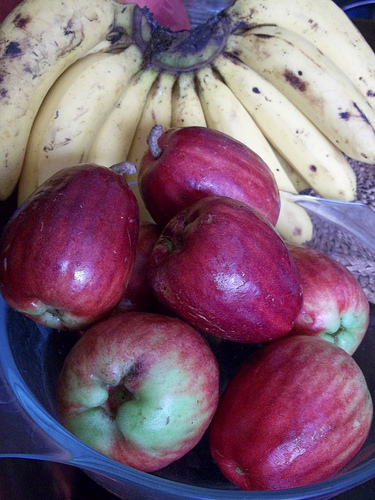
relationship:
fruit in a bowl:
[0, 1, 370, 492] [2, 193, 375, 499]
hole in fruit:
[98, 381, 135, 416] [53, 309, 222, 476]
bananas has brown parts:
[0, 0, 373, 247] [276, 66, 351, 123]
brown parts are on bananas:
[276, 66, 351, 123] [0, 0, 373, 247]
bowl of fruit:
[2, 193, 375, 499] [0, 1, 370, 492]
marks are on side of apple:
[158, 276, 231, 338] [153, 196, 305, 348]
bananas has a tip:
[0, 0, 373, 247] [277, 197, 317, 248]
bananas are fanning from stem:
[2, 3, 372, 244] [132, 3, 230, 73]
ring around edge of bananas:
[132, 3, 230, 73] [2, 3, 372, 244]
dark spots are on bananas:
[279, 65, 312, 96] [0, 0, 373, 247]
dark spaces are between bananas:
[139, 46, 244, 96] [2, 3, 372, 244]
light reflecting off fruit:
[54, 256, 92, 286] [0, 160, 147, 333]